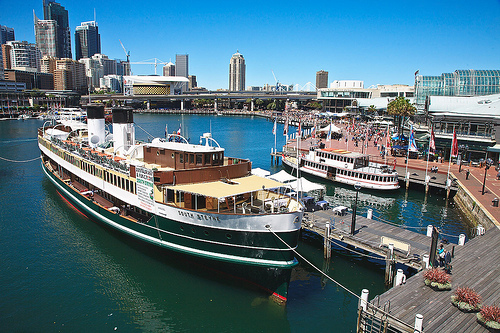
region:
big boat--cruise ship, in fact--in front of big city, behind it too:
[0, 0, 315, 282]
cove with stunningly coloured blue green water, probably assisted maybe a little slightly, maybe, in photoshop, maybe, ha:
[2, 104, 479, 330]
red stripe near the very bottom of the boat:
[259, 281, 294, 308]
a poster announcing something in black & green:
[125, 157, 159, 208]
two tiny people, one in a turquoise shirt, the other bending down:
[434, 241, 456, 271]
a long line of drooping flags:
[258, 109, 476, 194]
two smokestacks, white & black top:
[81, 98, 141, 159]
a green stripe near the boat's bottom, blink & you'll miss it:
[36, 164, 305, 284]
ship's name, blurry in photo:
[175, 205, 223, 228]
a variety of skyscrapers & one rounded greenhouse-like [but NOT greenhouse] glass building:
[2, 0, 499, 132]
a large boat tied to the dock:
[35, 105, 308, 281]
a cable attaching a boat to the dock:
[264, 225, 368, 302]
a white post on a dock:
[357, 285, 372, 312]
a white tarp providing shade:
[285, 177, 328, 195]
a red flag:
[448, 127, 463, 156]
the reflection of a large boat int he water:
[41, 176, 293, 332]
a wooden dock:
[305, 201, 499, 326]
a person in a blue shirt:
[436, 245, 448, 255]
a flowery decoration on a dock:
[448, 285, 483, 313]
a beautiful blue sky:
[0, 0, 497, 89]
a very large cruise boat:
[38, 110, 303, 291]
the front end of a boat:
[185, 187, 315, 275]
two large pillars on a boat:
[49, 89, 130, 159]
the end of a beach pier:
[291, 189, 438, 281]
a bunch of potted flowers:
[412, 264, 498, 315]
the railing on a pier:
[351, 290, 413, 332]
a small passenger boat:
[292, 138, 387, 198]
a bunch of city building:
[20, 10, 131, 103]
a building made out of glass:
[413, 65, 487, 106]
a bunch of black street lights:
[452, 126, 487, 209]